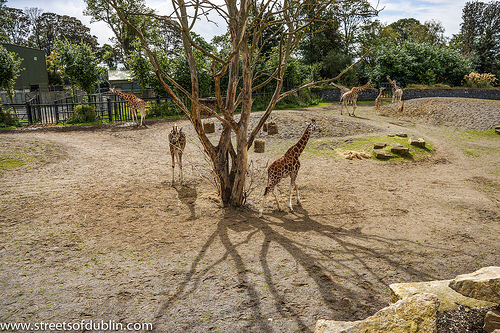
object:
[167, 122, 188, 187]
giraffe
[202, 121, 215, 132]
food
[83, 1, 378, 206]
tree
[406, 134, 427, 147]
rocks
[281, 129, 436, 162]
grass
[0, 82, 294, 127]
fence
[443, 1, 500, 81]
trees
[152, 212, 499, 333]
shadow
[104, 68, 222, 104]
building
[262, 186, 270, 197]
tip of tail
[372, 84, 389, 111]
baby giraffe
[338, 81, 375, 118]
adult giraffe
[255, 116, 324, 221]
young giraffe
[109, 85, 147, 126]
giraffe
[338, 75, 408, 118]
group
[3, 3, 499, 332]
zoo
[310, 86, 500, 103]
wall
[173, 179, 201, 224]
shadow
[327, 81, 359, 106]
giraffes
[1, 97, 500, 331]
ground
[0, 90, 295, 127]
metal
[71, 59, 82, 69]
leaves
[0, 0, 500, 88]
background